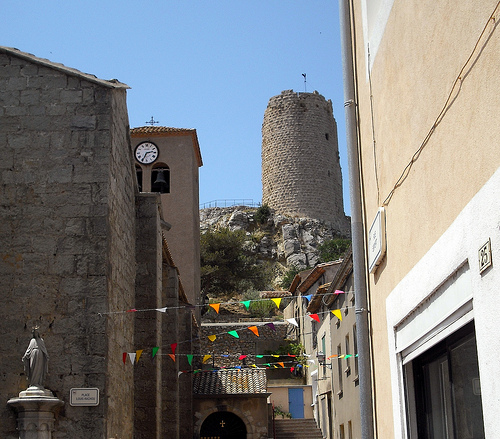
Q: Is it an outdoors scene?
A: Yes, it is outdoors.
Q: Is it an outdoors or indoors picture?
A: It is outdoors.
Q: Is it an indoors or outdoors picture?
A: It is outdoors.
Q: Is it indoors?
A: No, it is outdoors.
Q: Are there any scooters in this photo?
A: No, there are no scooters.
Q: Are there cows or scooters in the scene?
A: No, there are no scooters or cows.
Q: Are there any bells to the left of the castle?
A: Yes, there is a bell to the left of the castle.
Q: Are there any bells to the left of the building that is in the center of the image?
A: Yes, there is a bell to the left of the castle.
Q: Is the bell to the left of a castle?
A: Yes, the bell is to the left of a castle.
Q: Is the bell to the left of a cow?
A: No, the bell is to the left of a castle.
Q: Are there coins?
A: No, there are no coins.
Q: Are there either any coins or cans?
A: No, there are no coins or cans.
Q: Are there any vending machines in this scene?
A: No, there are no vending machines.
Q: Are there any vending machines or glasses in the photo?
A: No, there are no vending machines or glasses.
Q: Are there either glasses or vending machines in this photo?
A: No, there are no vending machines or glasses.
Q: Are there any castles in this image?
A: Yes, there is a castle.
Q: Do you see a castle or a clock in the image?
A: Yes, there is a castle.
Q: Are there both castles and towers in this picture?
A: Yes, there are both a castle and a tower.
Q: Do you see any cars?
A: No, there are no cars.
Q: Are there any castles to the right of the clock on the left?
A: Yes, there is a castle to the right of the clock.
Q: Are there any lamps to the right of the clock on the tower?
A: No, there is a castle to the right of the clock.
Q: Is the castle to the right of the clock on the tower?
A: Yes, the castle is to the right of the clock.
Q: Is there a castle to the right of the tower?
A: Yes, there is a castle to the right of the tower.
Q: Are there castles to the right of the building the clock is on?
A: Yes, there is a castle to the right of the tower.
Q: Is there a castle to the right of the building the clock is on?
A: Yes, there is a castle to the right of the tower.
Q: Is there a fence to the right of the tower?
A: No, there is a castle to the right of the tower.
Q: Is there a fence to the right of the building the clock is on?
A: No, there is a castle to the right of the tower.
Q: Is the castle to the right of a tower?
A: Yes, the castle is to the right of a tower.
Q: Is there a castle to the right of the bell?
A: Yes, there is a castle to the right of the bell.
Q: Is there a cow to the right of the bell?
A: No, there is a castle to the right of the bell.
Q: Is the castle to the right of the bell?
A: Yes, the castle is to the right of the bell.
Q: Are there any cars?
A: No, there are no cars.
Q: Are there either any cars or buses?
A: No, there are no cars or buses.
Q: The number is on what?
A: The number is on the building.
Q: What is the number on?
A: The number is on the building.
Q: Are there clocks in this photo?
A: Yes, there is a clock.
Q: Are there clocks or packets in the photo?
A: Yes, there is a clock.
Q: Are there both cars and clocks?
A: No, there is a clock but no cars.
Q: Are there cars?
A: No, there are no cars.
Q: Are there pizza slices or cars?
A: No, there are no cars or pizza slices.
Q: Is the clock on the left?
A: Yes, the clock is on the left of the image.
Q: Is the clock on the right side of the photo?
A: No, the clock is on the left of the image.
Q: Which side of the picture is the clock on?
A: The clock is on the left of the image.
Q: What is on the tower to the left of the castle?
A: The clock is on the tower.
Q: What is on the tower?
A: The clock is on the tower.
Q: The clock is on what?
A: The clock is on the tower.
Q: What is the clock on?
A: The clock is on the tower.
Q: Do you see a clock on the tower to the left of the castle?
A: Yes, there is a clock on the tower.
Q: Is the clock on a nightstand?
A: No, the clock is on the tower.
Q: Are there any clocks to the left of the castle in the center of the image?
A: Yes, there is a clock to the left of the castle.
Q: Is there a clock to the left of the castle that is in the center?
A: Yes, there is a clock to the left of the castle.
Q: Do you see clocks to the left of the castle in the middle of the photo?
A: Yes, there is a clock to the left of the castle.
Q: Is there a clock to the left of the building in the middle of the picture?
A: Yes, there is a clock to the left of the castle.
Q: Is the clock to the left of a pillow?
A: No, the clock is to the left of a castle.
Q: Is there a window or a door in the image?
A: Yes, there is a door.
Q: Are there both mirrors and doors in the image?
A: No, there is a door but no mirrors.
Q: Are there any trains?
A: No, there are no trains.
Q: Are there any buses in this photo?
A: No, there are no buses.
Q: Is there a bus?
A: No, there are no buses.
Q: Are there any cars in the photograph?
A: No, there are no cars.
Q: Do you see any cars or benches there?
A: No, there are no cars or benches.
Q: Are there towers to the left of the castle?
A: Yes, there is a tower to the left of the castle.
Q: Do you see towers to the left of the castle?
A: Yes, there is a tower to the left of the castle.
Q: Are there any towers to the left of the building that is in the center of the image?
A: Yes, there is a tower to the left of the castle.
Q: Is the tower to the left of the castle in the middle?
A: Yes, the tower is to the left of the castle.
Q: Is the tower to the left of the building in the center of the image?
A: Yes, the tower is to the left of the castle.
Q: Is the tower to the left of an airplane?
A: No, the tower is to the left of the castle.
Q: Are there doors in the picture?
A: Yes, there is a door.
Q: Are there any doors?
A: Yes, there is a door.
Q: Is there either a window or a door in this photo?
A: Yes, there is a door.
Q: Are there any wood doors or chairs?
A: Yes, there is a wood door.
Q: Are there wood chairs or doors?
A: Yes, there is a wood door.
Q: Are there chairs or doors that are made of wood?
A: Yes, the door is made of wood.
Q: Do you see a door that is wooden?
A: Yes, there is a wood door.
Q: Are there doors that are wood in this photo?
A: Yes, there is a wood door.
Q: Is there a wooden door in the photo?
A: Yes, there is a wood door.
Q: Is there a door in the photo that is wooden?
A: Yes, there is a door that is wooden.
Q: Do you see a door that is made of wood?
A: Yes, there is a door that is made of wood.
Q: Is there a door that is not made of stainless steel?
A: Yes, there is a door that is made of wood.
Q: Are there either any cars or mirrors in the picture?
A: No, there are no cars or mirrors.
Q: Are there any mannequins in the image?
A: No, there are no mannequins.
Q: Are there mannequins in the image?
A: No, there are no mannequins.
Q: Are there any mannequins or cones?
A: No, there are no mannequins or cones.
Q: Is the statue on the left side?
A: Yes, the statue is on the left of the image.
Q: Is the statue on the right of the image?
A: No, the statue is on the left of the image.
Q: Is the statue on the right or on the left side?
A: The statue is on the left of the image.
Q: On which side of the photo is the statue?
A: The statue is on the left of the image.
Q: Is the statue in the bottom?
A: Yes, the statue is in the bottom of the image.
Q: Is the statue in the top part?
A: No, the statue is in the bottom of the image.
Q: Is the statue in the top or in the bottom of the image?
A: The statue is in the bottom of the image.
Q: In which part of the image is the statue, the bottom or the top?
A: The statue is in the bottom of the image.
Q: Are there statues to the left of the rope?
A: Yes, there is a statue to the left of the rope.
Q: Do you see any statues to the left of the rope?
A: Yes, there is a statue to the left of the rope.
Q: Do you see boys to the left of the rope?
A: No, there is a statue to the left of the rope.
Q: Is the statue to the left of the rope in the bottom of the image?
A: Yes, the statue is to the left of the rope.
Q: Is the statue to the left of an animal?
A: No, the statue is to the left of the rope.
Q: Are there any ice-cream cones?
A: No, there are no ice-cream cones.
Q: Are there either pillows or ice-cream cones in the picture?
A: No, there are no ice-cream cones or pillows.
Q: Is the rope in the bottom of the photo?
A: Yes, the rope is in the bottom of the image.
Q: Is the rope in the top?
A: No, the rope is in the bottom of the image.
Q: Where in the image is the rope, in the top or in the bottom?
A: The rope is in the bottom of the image.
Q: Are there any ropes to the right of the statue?
A: Yes, there is a rope to the right of the statue.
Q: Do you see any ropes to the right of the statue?
A: Yes, there is a rope to the right of the statue.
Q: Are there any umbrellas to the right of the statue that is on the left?
A: No, there is a rope to the right of the statue.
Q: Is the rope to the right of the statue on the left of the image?
A: Yes, the rope is to the right of the statue.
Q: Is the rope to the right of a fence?
A: No, the rope is to the right of the statue.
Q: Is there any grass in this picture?
A: Yes, there is grass.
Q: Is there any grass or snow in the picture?
A: Yes, there is grass.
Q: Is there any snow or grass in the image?
A: Yes, there is grass.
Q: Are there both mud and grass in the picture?
A: No, there is grass but no mud.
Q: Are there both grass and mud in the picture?
A: No, there is grass but no mud.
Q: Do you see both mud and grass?
A: No, there is grass but no mud.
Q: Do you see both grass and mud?
A: No, there is grass but no mud.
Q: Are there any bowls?
A: No, there are no bowls.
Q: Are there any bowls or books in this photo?
A: No, there are no bowls or books.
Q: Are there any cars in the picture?
A: No, there are no cars.